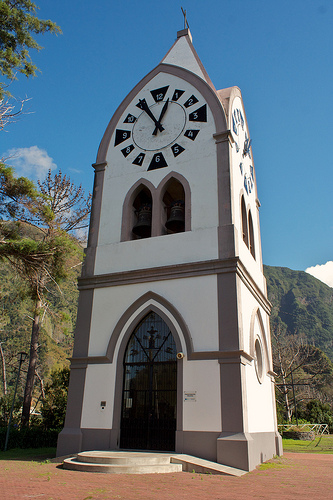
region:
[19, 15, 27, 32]
leaves on the tree.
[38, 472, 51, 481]
weeds in the bricks.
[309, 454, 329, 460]
path made of bricks.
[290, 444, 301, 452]
grass on the ground.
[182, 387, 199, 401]
sign on the building.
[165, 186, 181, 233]
bell in the tower.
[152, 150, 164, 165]
number on the clock.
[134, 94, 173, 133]
hands on the clock.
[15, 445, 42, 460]
shade on the ground.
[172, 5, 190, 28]
cross atop the tower.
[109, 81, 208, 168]
Clock reads 12:55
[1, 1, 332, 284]
Sun is shining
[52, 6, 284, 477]
Tower stands alone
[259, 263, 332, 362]
mountain is behind tower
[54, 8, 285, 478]
tower is in front of mountain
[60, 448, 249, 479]
building is wheelchair accessible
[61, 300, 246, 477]
door has stairs and a ramp leading to it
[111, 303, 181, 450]
doorway is arched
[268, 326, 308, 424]
tree is behind tower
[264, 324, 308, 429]
tree inbetween tower and mountain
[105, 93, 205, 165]
clock on the building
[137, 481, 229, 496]
the ground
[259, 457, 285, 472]
a patch of grass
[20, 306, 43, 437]
a tall tree trunk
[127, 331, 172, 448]
a door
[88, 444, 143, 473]
steps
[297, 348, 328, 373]
bushes that are green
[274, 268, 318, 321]
a big mountain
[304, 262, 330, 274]
a white cloud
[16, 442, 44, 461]
a shadow on the ground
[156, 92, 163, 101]
The number 12 on a clock.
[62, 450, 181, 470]
Two concrete steps up to the doorway.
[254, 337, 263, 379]
Round window on the bottom right.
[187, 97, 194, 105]
White number two in between the 1 and 3 on a clock.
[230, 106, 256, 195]
A blue clock face on the east side of the building.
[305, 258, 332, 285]
Extremely white cloud above a green hill.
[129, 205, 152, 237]
A large brass bell to the left of another.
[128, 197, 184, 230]
Two identical bells under a black clock.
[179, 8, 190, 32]
A large cross on the top of a tower.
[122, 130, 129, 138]
White number 9 on a clock.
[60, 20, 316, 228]
a clock on a building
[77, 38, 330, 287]
a large clock on a building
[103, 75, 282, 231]
an outside clock on a building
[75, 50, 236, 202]
a large outside clock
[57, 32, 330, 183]
a large outside clock on a building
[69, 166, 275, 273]
bells in a building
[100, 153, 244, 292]
a building with bells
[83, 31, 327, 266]
a building with bells and a clock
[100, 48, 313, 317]
clock and bells in a building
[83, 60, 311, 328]
a clock and building